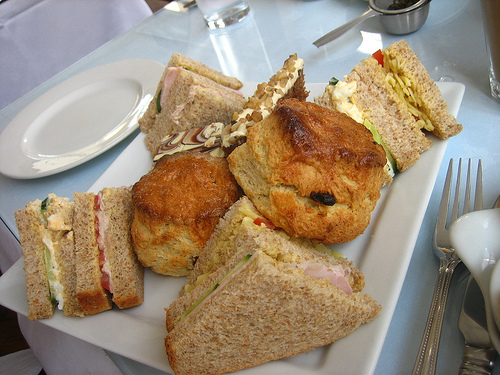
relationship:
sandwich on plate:
[156, 195, 365, 332] [0, 50, 173, 182]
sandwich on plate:
[314, 43, 463, 160] [0, 50, 173, 182]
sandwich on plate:
[135, 48, 243, 151] [0, 50, 173, 182]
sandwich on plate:
[14, 190, 83, 322] [0, 50, 173, 182]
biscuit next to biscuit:
[224, 98, 387, 244] [126, 148, 241, 292]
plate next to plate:
[0, 50, 173, 182] [3, 57, 464, 366]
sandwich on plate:
[156, 199, 379, 362] [3, 57, 464, 366]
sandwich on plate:
[314, 43, 463, 160] [3, 57, 464, 366]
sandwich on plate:
[144, 54, 248, 161] [3, 57, 464, 366]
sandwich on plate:
[6, 179, 146, 323] [3, 57, 464, 366]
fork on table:
[401, 154, 484, 374] [11, 8, 484, 366]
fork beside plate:
[401, 154, 484, 374] [3, 57, 464, 366]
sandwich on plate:
[152, 187, 372, 367] [0, 50, 173, 182]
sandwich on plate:
[314, 38, 465, 173] [0, 50, 173, 182]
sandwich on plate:
[137, 53, 243, 148] [0, 50, 173, 182]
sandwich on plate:
[5, 171, 151, 325] [0, 50, 173, 182]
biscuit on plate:
[231, 96, 391, 248] [3, 57, 464, 366]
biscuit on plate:
[122, 147, 258, 293] [3, 57, 464, 366]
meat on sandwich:
[95, 203, 115, 294] [75, 188, 146, 317]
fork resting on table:
[401, 154, 484, 374] [5, 2, 484, 324]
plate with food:
[3, 57, 464, 366] [14, 40, 437, 357]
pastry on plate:
[384, 69, 418, 111] [3, 57, 464, 366]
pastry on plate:
[228, 95, 395, 241] [3, 57, 464, 366]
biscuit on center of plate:
[130, 150, 236, 277] [3, 57, 464, 366]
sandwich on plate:
[75, 188, 146, 317] [3, 57, 464, 366]